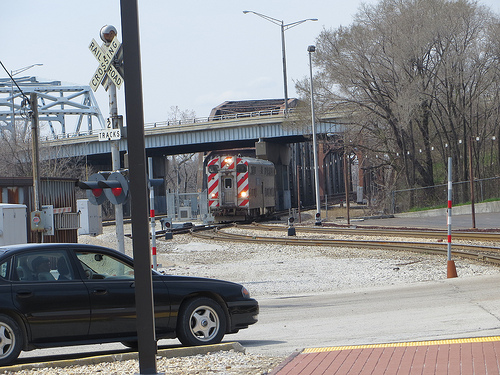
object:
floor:
[325, 115, 391, 134]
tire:
[175, 291, 229, 348]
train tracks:
[123, 192, 500, 268]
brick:
[271, 336, 500, 375]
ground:
[0, 201, 500, 375]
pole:
[447, 157, 453, 261]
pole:
[148, 157, 165, 271]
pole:
[308, 53, 321, 222]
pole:
[29, 93, 45, 243]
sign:
[98, 115, 121, 142]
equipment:
[77, 24, 129, 205]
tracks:
[222, 210, 491, 262]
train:
[195, 147, 284, 229]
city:
[0, 0, 500, 375]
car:
[0, 243, 260, 366]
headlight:
[241, 287, 251, 298]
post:
[281, 20, 288, 99]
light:
[242, 11, 248, 14]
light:
[311, 19, 318, 22]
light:
[92, 188, 102, 197]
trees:
[280, 0, 500, 215]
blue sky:
[0, 0, 500, 141]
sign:
[79, 172, 129, 205]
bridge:
[22, 108, 357, 160]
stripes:
[202, 158, 225, 206]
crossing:
[18, 210, 500, 375]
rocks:
[179, 249, 283, 270]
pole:
[118, 0, 159, 375]